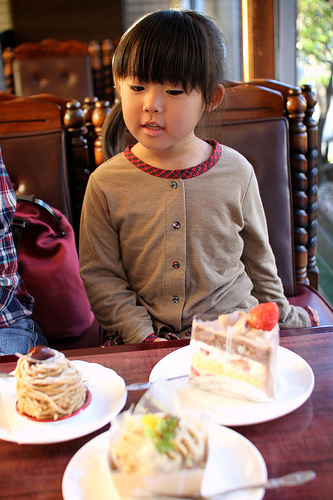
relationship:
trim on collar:
[118, 139, 229, 185] [123, 134, 222, 181]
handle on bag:
[12, 191, 59, 232] [11, 199, 100, 322]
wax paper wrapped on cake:
[237, 310, 282, 359] [165, 301, 292, 421]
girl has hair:
[77, 5, 302, 340] [100, 8, 232, 160]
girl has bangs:
[77, 5, 302, 340] [115, 12, 197, 94]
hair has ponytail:
[100, 8, 232, 160] [102, 100, 124, 161]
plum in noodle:
[25, 346, 55, 366] [9, 339, 90, 415]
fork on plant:
[155, 467, 317, 499] [60, 410, 267, 499]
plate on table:
[147, 342, 314, 424] [0, 354, 331, 498]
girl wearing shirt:
[77, 5, 302, 340] [78, 138, 317, 343]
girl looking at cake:
[77, 5, 302, 340] [175, 304, 318, 384]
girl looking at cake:
[77, 7, 320, 344] [188, 301, 281, 403]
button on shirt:
[168, 180, 182, 191] [77, 137, 317, 347]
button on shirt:
[169, 219, 180, 229] [77, 137, 317, 347]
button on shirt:
[170, 261, 181, 270] [77, 137, 317, 347]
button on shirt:
[171, 294, 181, 303] [77, 137, 317, 347]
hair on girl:
[109, 8, 226, 109] [61, 9, 291, 351]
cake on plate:
[188, 301, 281, 403] [136, 310, 316, 441]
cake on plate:
[9, 344, 85, 422] [0, 359, 126, 444]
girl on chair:
[77, 5, 302, 340] [86, 100, 320, 340]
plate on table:
[147, 342, 314, 424] [0, 324, 331, 498]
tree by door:
[297, 1, 332, 57] [242, 1, 321, 90]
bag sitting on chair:
[13, 188, 110, 343] [1, 86, 96, 351]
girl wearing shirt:
[77, 5, 302, 340] [77, 142, 300, 347]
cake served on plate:
[188, 301, 281, 403] [147, 344, 314, 425]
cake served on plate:
[9, 344, 91, 422] [0, 359, 126, 444]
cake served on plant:
[107, 411, 209, 498] [60, 410, 267, 499]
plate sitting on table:
[147, 344, 314, 425] [0, 324, 331, 498]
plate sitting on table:
[0, 359, 126, 444] [0, 324, 331, 498]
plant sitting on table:
[60, 410, 267, 499] [0, 324, 331, 498]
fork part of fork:
[155, 467, 317, 499] [155, 467, 317, 499]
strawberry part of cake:
[245, 301, 277, 330] [185, 311, 281, 403]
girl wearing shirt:
[77, 7, 320, 344] [78, 138, 317, 343]